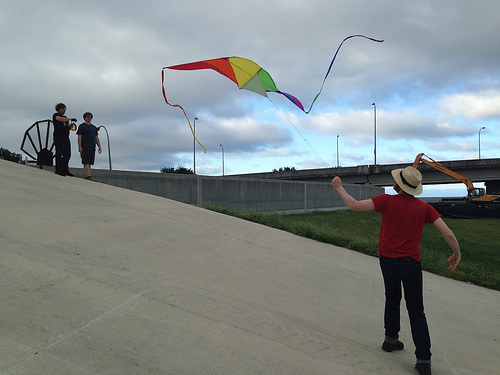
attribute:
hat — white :
[389, 160, 425, 195]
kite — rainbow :
[142, 43, 484, 367]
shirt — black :
[50, 109, 72, 143]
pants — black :
[54, 133, 73, 166]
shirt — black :
[73, 117, 103, 144]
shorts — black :
[77, 141, 100, 163]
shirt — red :
[368, 184, 441, 264]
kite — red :
[157, 30, 383, 141]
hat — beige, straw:
[391, 165, 423, 195]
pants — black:
[379, 255, 430, 364]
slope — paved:
[1, 159, 498, 373]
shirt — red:
[371, 193, 441, 263]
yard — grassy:
[198, 203, 498, 288]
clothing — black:
[76, 121, 98, 166]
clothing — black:
[50, 113, 71, 175]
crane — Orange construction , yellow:
[404, 152, 498, 221]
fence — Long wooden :
[81, 162, 386, 211]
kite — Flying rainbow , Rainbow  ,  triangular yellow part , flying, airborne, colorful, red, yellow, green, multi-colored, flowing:
[124, 29, 392, 141]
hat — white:
[387, 160, 433, 205]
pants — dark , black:
[370, 255, 443, 353]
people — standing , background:
[46, 103, 115, 181]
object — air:
[128, 26, 384, 147]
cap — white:
[386, 164, 433, 194]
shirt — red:
[364, 191, 434, 253]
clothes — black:
[48, 111, 79, 183]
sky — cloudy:
[3, 2, 159, 103]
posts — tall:
[182, 110, 249, 179]